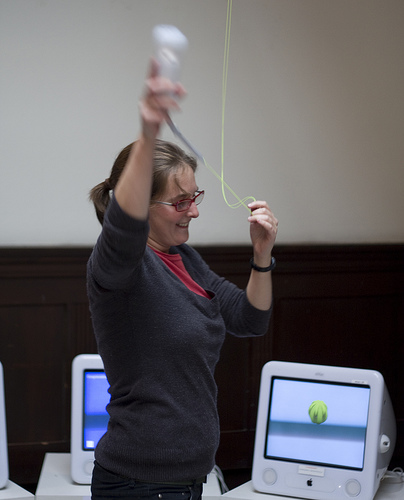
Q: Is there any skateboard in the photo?
A: No, there are no skateboards.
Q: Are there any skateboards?
A: No, there are no skateboards.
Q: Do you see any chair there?
A: No, there are no chairs.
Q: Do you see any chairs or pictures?
A: No, there are no chairs or pictures.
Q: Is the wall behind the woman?
A: Yes, the wall is behind the woman.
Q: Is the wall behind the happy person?
A: Yes, the wall is behind the woman.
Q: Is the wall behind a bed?
A: No, the wall is behind the woman.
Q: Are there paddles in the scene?
A: No, there are no paddles.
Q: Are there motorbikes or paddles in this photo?
A: No, there are no paddles or motorbikes.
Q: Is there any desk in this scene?
A: Yes, there is a desk.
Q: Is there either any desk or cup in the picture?
A: Yes, there is a desk.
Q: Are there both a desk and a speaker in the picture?
A: No, there is a desk but no speakers.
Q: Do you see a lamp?
A: No, there are no lamps.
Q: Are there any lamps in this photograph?
A: No, there are no lamps.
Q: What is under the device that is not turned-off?
A: The desk is under the computer.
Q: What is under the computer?
A: The desk is under the computer.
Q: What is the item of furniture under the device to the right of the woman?
A: The piece of furniture is a desk.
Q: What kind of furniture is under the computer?
A: The piece of furniture is a desk.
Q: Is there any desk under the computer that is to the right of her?
A: Yes, there is a desk under the computer.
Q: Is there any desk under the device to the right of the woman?
A: Yes, there is a desk under the computer.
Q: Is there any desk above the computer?
A: No, the desk is under the computer.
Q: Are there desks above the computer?
A: No, the desk is under the computer.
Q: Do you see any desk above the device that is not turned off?
A: No, the desk is under the computer.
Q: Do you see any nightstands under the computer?
A: No, there is a desk under the computer.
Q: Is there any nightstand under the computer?
A: No, there is a desk under the computer.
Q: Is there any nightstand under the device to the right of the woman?
A: No, there is a desk under the computer.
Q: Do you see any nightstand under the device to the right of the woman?
A: No, there is a desk under the computer.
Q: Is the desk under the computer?
A: Yes, the desk is under the computer.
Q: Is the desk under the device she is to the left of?
A: Yes, the desk is under the computer.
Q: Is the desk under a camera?
A: No, the desk is under the computer.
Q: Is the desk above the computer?
A: No, the desk is under the computer.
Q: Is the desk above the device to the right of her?
A: No, the desk is under the computer.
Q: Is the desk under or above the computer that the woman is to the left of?
A: The desk is under the computer.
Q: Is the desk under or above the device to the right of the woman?
A: The desk is under the computer.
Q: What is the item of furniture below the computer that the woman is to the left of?
A: The piece of furniture is a desk.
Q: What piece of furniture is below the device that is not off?
A: The piece of furniture is a desk.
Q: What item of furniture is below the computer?
A: The piece of furniture is a desk.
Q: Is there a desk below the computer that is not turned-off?
A: Yes, there is a desk below the computer.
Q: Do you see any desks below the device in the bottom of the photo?
A: Yes, there is a desk below the computer.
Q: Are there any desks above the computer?
A: No, the desk is below the computer.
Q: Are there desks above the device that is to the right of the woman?
A: No, the desk is below the computer.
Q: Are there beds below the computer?
A: No, there is a desk below the computer.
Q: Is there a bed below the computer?
A: No, there is a desk below the computer.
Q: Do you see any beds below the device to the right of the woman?
A: No, there is a desk below the computer.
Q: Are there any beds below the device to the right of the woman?
A: No, there is a desk below the computer.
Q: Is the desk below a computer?
A: Yes, the desk is below a computer.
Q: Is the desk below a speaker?
A: No, the desk is below a computer.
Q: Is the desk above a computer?
A: No, the desk is below a computer.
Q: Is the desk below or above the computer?
A: The desk is below the computer.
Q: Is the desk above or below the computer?
A: The desk is below the computer.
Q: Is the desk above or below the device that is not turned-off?
A: The desk is below the computer.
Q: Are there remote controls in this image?
A: Yes, there is a remote control.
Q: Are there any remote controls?
A: Yes, there is a remote control.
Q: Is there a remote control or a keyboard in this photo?
A: Yes, there is a remote control.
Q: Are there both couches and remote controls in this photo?
A: No, there is a remote control but no couches.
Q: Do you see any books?
A: No, there are no books.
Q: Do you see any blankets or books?
A: No, there are no books or blankets.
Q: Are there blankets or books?
A: No, there are no books or blankets.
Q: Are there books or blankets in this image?
A: No, there are no books or blankets.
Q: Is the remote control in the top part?
A: Yes, the remote control is in the top of the image.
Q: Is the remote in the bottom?
A: No, the remote is in the top of the image.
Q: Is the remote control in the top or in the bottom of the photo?
A: The remote control is in the top of the image.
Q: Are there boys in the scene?
A: No, there are no boys.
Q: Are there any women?
A: Yes, there is a woman.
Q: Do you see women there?
A: Yes, there is a woman.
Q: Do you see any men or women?
A: Yes, there is a woman.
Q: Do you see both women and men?
A: No, there is a woman but no men.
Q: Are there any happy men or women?
A: Yes, there is a happy woman.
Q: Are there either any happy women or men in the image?
A: Yes, there is a happy woman.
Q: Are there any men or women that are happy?
A: Yes, the woman is happy.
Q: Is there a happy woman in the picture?
A: Yes, there is a happy woman.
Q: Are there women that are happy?
A: Yes, there is a woman that is happy.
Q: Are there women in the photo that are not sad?
A: Yes, there is a happy woman.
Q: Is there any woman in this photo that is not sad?
A: Yes, there is a happy woman.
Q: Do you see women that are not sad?
A: Yes, there is a happy woman.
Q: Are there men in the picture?
A: No, there are no men.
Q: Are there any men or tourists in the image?
A: No, there are no men or tourists.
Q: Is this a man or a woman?
A: This is a woman.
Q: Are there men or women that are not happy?
A: No, there is a woman but she is happy.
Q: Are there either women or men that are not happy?
A: No, there is a woman but she is happy.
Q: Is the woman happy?
A: Yes, the woman is happy.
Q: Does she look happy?
A: Yes, the woman is happy.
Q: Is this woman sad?
A: No, the woman is happy.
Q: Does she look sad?
A: No, the woman is happy.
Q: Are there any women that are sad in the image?
A: No, there is a woman but she is happy.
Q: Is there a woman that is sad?
A: No, there is a woman but she is happy.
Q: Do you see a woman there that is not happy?
A: No, there is a woman but she is happy.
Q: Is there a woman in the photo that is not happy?
A: No, there is a woman but she is happy.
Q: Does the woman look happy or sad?
A: The woman is happy.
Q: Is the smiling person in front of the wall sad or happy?
A: The woman is happy.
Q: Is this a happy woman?
A: Yes, this is a happy woman.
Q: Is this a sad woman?
A: No, this is a happy woman.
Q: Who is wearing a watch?
A: The woman is wearing a watch.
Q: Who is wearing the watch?
A: The woman is wearing a watch.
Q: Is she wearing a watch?
A: Yes, the woman is wearing a watch.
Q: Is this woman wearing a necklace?
A: No, the woman is wearing a watch.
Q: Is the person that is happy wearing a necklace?
A: No, the woman is wearing a watch.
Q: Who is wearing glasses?
A: The woman is wearing glasses.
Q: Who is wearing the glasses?
A: The woman is wearing glasses.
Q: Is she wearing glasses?
A: Yes, the woman is wearing glasses.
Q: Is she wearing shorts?
A: No, the woman is wearing glasses.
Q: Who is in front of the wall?
A: The woman is in front of the wall.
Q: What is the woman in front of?
A: The woman is in front of the wall.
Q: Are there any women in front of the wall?
A: Yes, there is a woman in front of the wall.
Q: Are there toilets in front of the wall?
A: No, there is a woman in front of the wall.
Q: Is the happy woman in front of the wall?
A: Yes, the woman is in front of the wall.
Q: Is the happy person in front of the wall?
A: Yes, the woman is in front of the wall.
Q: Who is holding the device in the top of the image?
A: The woman is holding the remote control.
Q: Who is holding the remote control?
A: The woman is holding the remote control.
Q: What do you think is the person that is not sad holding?
A: The woman is holding the remote.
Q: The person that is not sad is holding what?
A: The woman is holding the remote.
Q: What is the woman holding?
A: The woman is holding the remote.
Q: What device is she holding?
A: The woman is holding the remote.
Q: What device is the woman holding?
A: The woman is holding the remote.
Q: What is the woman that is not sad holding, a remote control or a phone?
A: The woman is holding a remote control.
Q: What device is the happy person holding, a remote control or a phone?
A: The woman is holding a remote control.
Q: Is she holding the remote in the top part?
A: Yes, the woman is holding the remote.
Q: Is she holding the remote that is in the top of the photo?
A: Yes, the woman is holding the remote.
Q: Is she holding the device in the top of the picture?
A: Yes, the woman is holding the remote.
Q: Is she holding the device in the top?
A: Yes, the woman is holding the remote.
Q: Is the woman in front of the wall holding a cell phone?
A: No, the woman is holding the remote.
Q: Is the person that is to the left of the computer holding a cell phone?
A: No, the woman is holding the remote.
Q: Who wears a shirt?
A: The woman wears a shirt.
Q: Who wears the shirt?
A: The woman wears a shirt.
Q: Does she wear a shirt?
A: Yes, the woman wears a shirt.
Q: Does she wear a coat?
A: No, the woman wears a shirt.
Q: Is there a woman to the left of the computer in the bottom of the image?
A: Yes, there is a woman to the left of the computer.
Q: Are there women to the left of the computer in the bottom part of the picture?
A: Yes, there is a woman to the left of the computer.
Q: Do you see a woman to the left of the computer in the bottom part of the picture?
A: Yes, there is a woman to the left of the computer.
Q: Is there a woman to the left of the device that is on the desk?
A: Yes, there is a woman to the left of the computer.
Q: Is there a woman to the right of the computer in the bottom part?
A: No, the woman is to the left of the computer.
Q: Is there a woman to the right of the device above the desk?
A: No, the woman is to the left of the computer.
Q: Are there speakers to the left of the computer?
A: No, there is a woman to the left of the computer.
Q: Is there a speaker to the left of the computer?
A: No, there is a woman to the left of the computer.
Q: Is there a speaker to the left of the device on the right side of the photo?
A: No, there is a woman to the left of the computer.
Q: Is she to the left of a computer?
A: Yes, the woman is to the left of a computer.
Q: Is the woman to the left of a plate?
A: No, the woman is to the left of a computer.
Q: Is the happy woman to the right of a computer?
A: No, the woman is to the left of a computer.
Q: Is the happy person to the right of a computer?
A: No, the woman is to the left of a computer.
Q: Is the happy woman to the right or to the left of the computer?
A: The woman is to the left of the computer.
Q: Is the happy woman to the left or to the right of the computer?
A: The woman is to the left of the computer.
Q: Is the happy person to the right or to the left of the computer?
A: The woman is to the left of the computer.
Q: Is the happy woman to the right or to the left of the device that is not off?
A: The woman is to the left of the computer.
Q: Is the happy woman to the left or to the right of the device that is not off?
A: The woman is to the left of the computer.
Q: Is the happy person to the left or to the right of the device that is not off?
A: The woman is to the left of the computer.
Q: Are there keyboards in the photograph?
A: No, there are no keyboards.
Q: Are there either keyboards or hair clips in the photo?
A: No, there are no keyboards or hair clips.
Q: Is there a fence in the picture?
A: No, there are no fences.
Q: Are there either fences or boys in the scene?
A: No, there are no fences or boys.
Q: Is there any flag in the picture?
A: No, there are no flags.